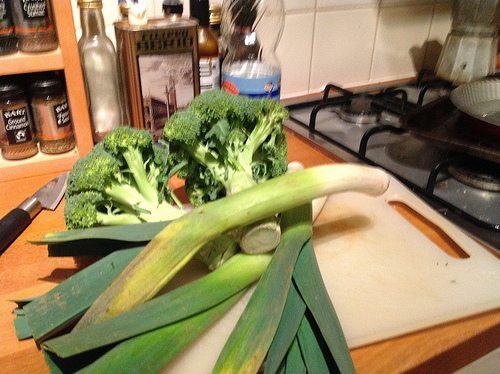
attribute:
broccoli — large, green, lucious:
[56, 92, 299, 251]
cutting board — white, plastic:
[62, 161, 495, 373]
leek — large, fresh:
[16, 164, 397, 373]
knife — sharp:
[2, 167, 72, 263]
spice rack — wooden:
[1, 1, 95, 185]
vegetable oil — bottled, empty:
[213, 2, 292, 115]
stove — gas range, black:
[280, 68, 499, 225]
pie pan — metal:
[447, 73, 499, 132]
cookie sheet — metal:
[399, 103, 497, 159]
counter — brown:
[6, 160, 461, 370]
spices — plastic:
[5, 80, 69, 154]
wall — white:
[284, 1, 427, 80]